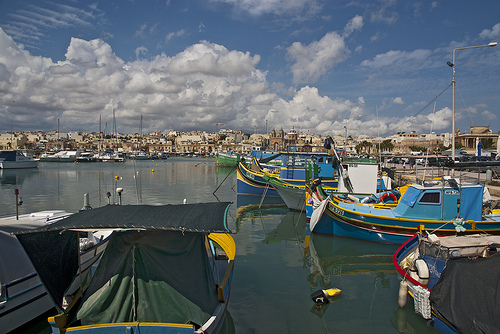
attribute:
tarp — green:
[96, 243, 233, 333]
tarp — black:
[78, 199, 241, 251]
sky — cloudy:
[202, 25, 271, 56]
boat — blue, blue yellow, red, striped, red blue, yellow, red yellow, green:
[318, 186, 496, 262]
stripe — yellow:
[345, 201, 490, 223]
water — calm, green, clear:
[236, 245, 306, 306]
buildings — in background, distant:
[301, 138, 494, 152]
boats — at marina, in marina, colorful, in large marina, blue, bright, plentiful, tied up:
[230, 157, 484, 272]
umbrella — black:
[315, 133, 358, 160]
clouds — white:
[159, 54, 234, 117]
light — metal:
[6, 178, 29, 235]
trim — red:
[388, 237, 416, 290]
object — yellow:
[293, 294, 400, 325]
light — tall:
[435, 38, 463, 160]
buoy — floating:
[294, 269, 348, 326]